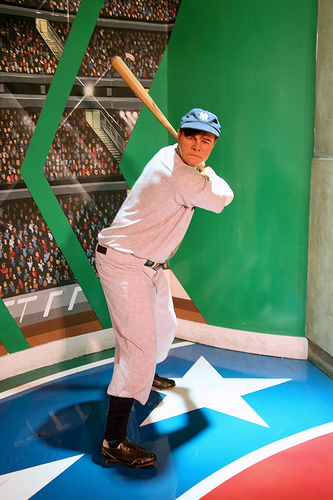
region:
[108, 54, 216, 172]
wooden baseball bat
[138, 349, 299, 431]
white star on floor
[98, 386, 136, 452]
black socks on leg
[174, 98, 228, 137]
blue baseball hat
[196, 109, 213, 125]
white logo on baseball hat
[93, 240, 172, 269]
black belt around waist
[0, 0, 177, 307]
colorful illustration of fans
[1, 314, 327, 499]
stars against blue background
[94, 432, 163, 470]
dark colored shoes on player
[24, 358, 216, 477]
shadow of baseball player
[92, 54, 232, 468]
image of Babe Ruth holding a baseball bat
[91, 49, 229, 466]
image of a baseball player wearing a white uniform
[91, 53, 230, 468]
image of a baseball player in a blue cap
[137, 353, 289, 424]
the white star with a shoe on it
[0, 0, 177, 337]
painted backdrop of people in bleachers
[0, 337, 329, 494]
painted floor the baseball player is on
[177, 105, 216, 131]
the blue baseball cap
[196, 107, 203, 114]
the white logo on the baseball cap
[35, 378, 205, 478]
shadow cast by the baseball player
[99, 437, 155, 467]
the brown shoe in the foreground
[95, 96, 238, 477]
figure of Babe Ruth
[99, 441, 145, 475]
player wearing black cleats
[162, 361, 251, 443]
a large white star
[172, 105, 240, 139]
wearing a new york hat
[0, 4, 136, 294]
picture of fans in stands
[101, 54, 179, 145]
player holding wooden bat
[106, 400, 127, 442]
player is wearing black socks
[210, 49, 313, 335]
green wall in background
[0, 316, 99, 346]
wood on base of floor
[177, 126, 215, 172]
face is made of wax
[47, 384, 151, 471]
shadow on the ground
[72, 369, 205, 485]
shadow on the ground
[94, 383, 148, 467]
the sock is black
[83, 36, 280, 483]
wax figure of a baseball player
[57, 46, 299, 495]
a wax statue of a baseball player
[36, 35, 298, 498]
a wax figure of Babe Ruth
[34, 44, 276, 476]
a wax statue of Babe Ruth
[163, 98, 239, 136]
a blue baseball cap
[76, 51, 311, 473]
a life-like wax figure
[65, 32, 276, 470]
a life size wax statue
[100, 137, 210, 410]
a white baseball uniform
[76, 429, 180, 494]
black leather cleats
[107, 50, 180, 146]
a wooden baseball bat